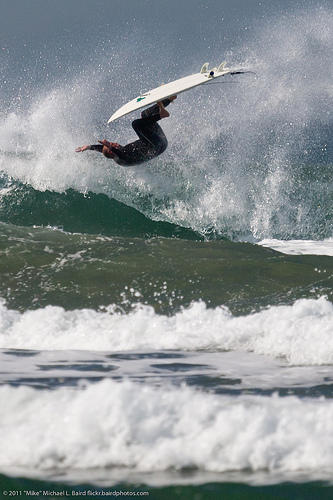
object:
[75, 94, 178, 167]
man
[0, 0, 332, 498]
ocean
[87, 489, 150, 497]
flickr address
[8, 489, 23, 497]
stamp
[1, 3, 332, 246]
water spray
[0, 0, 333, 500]
water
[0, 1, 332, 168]
sky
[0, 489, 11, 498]
symbol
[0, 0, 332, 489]
beach scene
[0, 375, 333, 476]
waves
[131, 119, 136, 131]
knees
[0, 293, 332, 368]
waves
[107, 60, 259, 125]
surfboard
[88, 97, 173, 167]
wetsuit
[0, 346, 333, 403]
foam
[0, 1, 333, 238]
wave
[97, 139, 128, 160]
arm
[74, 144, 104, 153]
arm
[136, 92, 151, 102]
design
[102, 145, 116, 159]
head